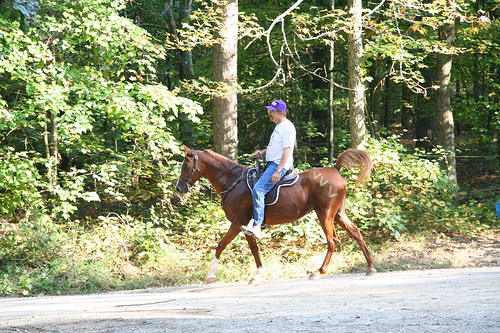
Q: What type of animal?
A: Horse.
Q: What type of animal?
A: Horse.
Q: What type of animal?
A: Horse.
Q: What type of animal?
A: Horse.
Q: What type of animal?
A: Horse.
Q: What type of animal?
A: Horse.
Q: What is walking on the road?
A: A horse.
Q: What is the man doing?
A: Riding a horse.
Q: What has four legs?
A: Horse.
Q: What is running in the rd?
A: A brown horse.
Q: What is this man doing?
A: Riding a horse.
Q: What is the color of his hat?
A: Purple.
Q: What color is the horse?
A: Brown.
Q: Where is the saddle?
A: On the horse.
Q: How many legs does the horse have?
A: Four.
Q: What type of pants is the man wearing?
A: Jeans.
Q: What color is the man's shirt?
A: White.